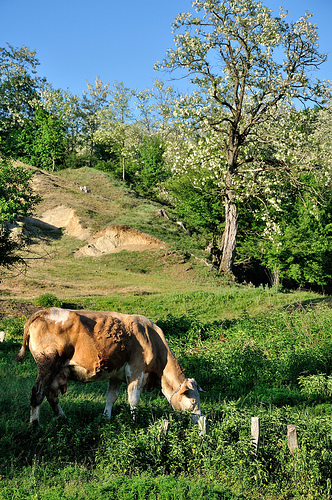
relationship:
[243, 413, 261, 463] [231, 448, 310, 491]
post in ground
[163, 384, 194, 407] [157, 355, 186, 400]
rope on cow's neck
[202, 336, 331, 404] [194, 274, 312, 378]
shadow on grass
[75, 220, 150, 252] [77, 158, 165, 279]
sand in hill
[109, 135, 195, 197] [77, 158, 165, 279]
trees in hill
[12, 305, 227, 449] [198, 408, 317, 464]
cow outside fence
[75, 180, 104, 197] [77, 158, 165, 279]
rock on hill